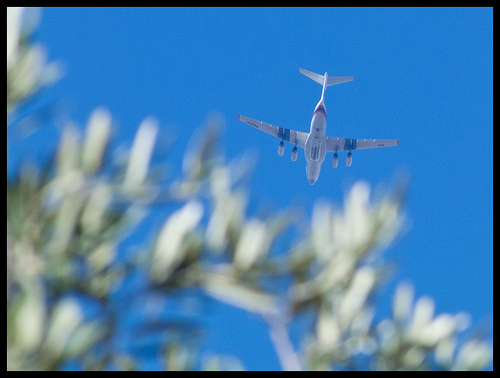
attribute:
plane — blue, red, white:
[243, 83, 388, 181]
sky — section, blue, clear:
[15, 13, 479, 367]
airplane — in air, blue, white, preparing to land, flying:
[256, 74, 399, 197]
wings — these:
[247, 114, 391, 150]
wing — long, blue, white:
[326, 137, 403, 155]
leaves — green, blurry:
[27, 185, 123, 246]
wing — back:
[293, 63, 369, 96]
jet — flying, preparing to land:
[250, 63, 409, 182]